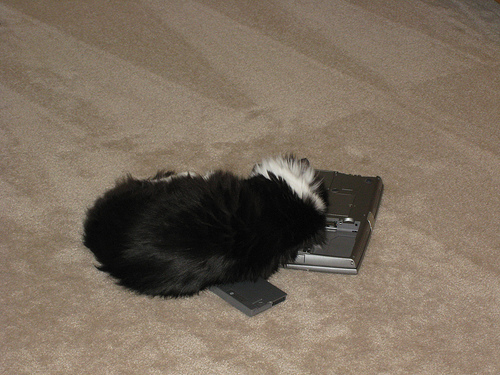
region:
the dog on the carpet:
[83, 150, 329, 298]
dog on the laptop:
[85, 139, 333, 287]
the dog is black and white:
[75, 150, 316, 295]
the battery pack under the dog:
[207, 275, 287, 322]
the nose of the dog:
[301, 153, 314, 166]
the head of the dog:
[235, 158, 345, 245]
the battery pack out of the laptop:
[210, 269, 305, 334]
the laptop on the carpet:
[292, 157, 399, 284]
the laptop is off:
[271, 150, 391, 290]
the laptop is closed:
[287, 151, 391, 288]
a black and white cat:
[53, 112, 353, 304]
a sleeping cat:
[28, 107, 383, 332]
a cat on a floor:
[48, 119, 404, 331]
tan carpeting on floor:
[11, 0, 493, 346]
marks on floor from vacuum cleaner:
[24, 6, 491, 162]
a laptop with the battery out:
[172, 123, 404, 329]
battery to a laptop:
[192, 249, 311, 329]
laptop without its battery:
[262, 154, 397, 278]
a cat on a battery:
[8, 72, 337, 337]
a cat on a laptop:
[72, 87, 439, 310]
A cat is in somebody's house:
[23, 31, 488, 371]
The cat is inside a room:
[25, 36, 460, 338]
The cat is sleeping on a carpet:
[40, 50, 445, 330]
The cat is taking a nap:
[60, 40, 426, 332]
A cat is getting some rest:
[40, 56, 440, 347]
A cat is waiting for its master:
[41, 53, 464, 370]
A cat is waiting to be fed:
[57, 61, 493, 346]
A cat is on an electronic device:
[26, 60, 454, 355]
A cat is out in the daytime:
[35, 56, 461, 361]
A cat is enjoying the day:
[55, 57, 470, 346]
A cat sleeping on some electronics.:
[50, 110, 427, 326]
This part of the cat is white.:
[253, 152, 319, 202]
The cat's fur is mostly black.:
[156, 204, 248, 243]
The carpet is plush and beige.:
[60, 82, 137, 142]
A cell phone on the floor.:
[210, 283, 292, 321]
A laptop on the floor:
[278, 143, 395, 288]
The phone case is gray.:
[238, 288, 258, 302]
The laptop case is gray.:
[338, 171, 368, 201]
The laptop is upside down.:
[256, 144, 412, 291]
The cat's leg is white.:
[163, 157, 208, 188]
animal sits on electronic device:
[78, 152, 325, 302]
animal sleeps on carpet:
[78, 152, 328, 303]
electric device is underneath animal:
[285, 166, 390, 274]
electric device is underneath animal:
[210, 276, 289, 317]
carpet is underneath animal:
[1, 2, 496, 374]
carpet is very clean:
[1, 1, 498, 373]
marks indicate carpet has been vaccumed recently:
[143, 1, 284, 141]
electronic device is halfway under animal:
[208, 275, 293, 320]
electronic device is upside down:
[276, 167, 388, 272]